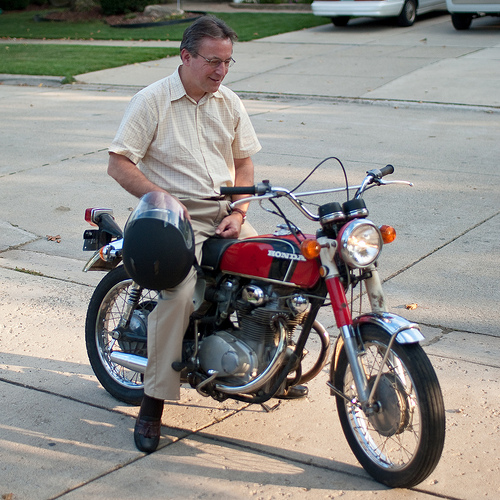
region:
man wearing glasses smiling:
[110, 11, 270, 106]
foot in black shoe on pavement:
[56, 331, 191, 467]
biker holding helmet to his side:
[91, 16, 271, 301]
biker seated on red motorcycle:
[95, 16, 270, 357]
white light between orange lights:
[295, 210, 410, 270]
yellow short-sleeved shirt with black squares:
[90, 65, 270, 205]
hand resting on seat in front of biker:
[141, 195, 278, 265]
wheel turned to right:
[250, 170, 460, 485]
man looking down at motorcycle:
[155, 16, 365, 281]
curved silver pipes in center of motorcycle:
[211, 290, 331, 430]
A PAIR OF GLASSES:
[188, 48, 245, 71]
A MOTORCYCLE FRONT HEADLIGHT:
[332, 208, 396, 272]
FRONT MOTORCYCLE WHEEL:
[321, 301, 449, 493]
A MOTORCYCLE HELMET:
[116, 187, 202, 296]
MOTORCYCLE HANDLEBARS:
[215, 161, 419, 213]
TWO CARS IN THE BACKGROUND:
[302, 0, 497, 40]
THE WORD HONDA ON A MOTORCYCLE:
[256, 237, 336, 272]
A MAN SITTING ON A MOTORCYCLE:
[49, 0, 486, 496]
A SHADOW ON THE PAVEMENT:
[3, 343, 357, 495]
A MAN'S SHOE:
[123, 413, 171, 456]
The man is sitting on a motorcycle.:
[43, 13, 468, 497]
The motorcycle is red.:
[64, 137, 486, 491]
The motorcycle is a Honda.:
[258, 235, 320, 267]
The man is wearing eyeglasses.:
[160, 19, 255, 103]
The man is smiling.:
[192, 66, 243, 91]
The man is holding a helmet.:
[100, 187, 205, 303]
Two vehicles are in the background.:
[300, 0, 498, 47]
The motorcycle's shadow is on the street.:
[0, 340, 403, 499]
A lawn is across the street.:
[0, 3, 301, 76]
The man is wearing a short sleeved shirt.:
[102, 69, 269, 216]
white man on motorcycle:
[19, 15, 473, 493]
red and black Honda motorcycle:
[61, 190, 473, 488]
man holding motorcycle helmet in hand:
[106, 9, 302, 310]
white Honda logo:
[263, 242, 316, 271]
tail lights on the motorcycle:
[74, 195, 129, 298]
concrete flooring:
[424, 181, 499, 296]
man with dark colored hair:
[151, 10, 258, 113]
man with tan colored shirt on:
[104, 12, 269, 271]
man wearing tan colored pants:
[97, 3, 270, 418]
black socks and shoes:
[113, 387, 187, 482]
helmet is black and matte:
[108, 196, 206, 300]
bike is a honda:
[211, 202, 336, 299]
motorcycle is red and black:
[64, 187, 456, 469]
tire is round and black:
[327, 293, 460, 490]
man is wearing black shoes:
[127, 376, 170, 468]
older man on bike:
[107, 45, 253, 482]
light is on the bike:
[333, 210, 388, 259]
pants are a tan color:
[126, 177, 269, 415]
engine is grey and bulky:
[181, 310, 305, 397]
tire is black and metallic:
[74, 263, 176, 410]